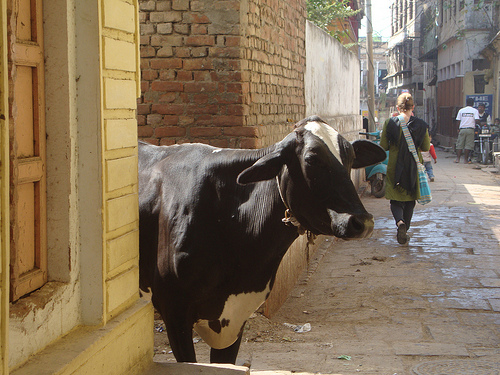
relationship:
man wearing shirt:
[451, 97, 481, 165] [449, 107, 484, 130]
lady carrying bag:
[363, 90, 440, 248] [392, 110, 433, 205]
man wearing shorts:
[451, 94, 490, 167] [450, 128, 477, 156]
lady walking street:
[378, 91, 433, 248] [156, 141, 498, 370]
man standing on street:
[451, 97, 481, 165] [156, 141, 498, 370]